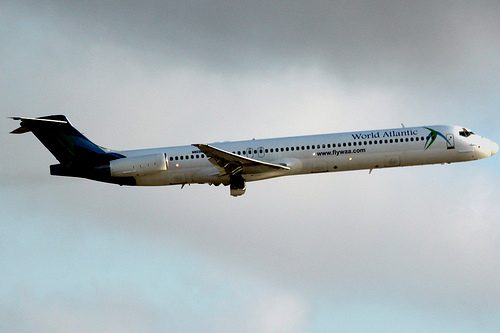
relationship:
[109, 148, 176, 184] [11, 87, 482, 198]
engine on airplane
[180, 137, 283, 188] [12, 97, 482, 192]
wing on airplane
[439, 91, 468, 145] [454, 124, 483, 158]
sun shining nose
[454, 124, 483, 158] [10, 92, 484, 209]
nose on airplane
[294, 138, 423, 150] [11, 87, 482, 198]
windows on airplane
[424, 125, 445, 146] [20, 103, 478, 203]
design on airplane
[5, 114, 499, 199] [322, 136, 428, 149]
airplane has windows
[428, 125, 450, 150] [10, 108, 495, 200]
logo on plane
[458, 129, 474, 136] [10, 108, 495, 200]
windshield on plane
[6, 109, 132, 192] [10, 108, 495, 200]
tail of plane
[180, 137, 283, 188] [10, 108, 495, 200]
wing of plane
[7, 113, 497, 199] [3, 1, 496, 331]
airplane flying in sky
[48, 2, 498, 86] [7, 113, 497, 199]
dark cloud above airplane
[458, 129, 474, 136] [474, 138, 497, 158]
windshield above nose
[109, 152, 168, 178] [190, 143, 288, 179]
engine behind wing